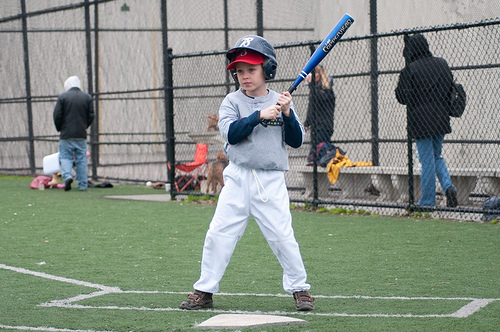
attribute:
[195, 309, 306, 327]
home base — white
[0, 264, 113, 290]
line — white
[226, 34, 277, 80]
helmet — black, lettered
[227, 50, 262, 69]
baseball hat — red, white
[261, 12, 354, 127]
baseball bat — blue, being held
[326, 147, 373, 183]
jacket — yellow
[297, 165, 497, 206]
bench — cement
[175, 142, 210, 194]
seat — red, open, pop up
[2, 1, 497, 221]
fence — chain link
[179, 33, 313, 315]
kid — playing, standing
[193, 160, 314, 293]
pants — white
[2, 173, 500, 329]
grass — green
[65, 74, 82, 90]
hood — over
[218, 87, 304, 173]
shirt — grey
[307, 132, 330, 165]
jeans — blue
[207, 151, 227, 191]
dog — brown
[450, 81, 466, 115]
backpack — black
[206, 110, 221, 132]
dog — brown